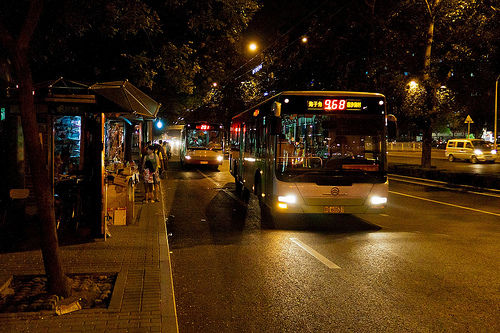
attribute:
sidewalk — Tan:
[1, 172, 177, 332]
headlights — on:
[472, 147, 499, 158]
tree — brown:
[4, 4, 74, 297]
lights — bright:
[354, 188, 401, 233]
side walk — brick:
[0, 179, 180, 331]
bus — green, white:
[201, 69, 419, 234]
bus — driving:
[178, 122, 228, 168]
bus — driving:
[222, 93, 391, 219]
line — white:
[286, 231, 343, 271]